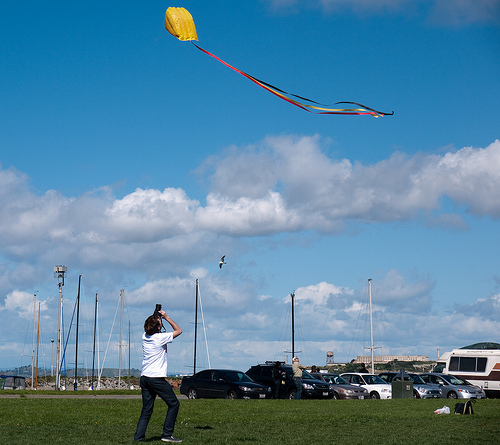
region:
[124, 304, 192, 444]
man is photographing kite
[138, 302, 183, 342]
man is holding camera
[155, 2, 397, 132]
yellow kite in the sky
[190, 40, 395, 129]
kite has long colorful tail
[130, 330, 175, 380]
man wearing white shirt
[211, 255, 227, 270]
seagull flying in sky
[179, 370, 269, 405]
black car is parked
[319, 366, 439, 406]
white car parked next to silver car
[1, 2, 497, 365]
sky is deep blue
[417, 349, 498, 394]
van is parked next to car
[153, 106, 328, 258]
white clouds in the sky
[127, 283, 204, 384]
person taking a photo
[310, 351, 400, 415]
cars parked on the street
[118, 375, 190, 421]
pants on the man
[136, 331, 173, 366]
white shirt on the man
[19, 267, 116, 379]
tall poles next to cars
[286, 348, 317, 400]
person looking up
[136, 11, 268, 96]
object in the air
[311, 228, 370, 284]
blue sky behind clouds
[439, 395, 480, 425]
bag on the ground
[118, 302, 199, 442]
the man with camera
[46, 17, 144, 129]
the sky is blue and clear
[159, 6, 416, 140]
the balloon in the sky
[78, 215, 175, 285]
the clouds in the sky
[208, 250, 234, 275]
the bird in the sky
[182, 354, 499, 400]
the cars are parked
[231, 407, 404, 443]
the grass is green and cut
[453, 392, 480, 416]
the bag on the grass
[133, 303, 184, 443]
the man wearing jeans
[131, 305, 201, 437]
the man wearing a t shirt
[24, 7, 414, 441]
person flying kit on grass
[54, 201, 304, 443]
man holding a camera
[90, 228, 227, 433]
man holding a camera up for picture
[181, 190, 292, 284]
seagull flying in the air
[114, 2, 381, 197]
yellow kite in the air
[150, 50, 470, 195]
tail of yellow kite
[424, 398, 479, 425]
objects laying on the ground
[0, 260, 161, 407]
masts of sail boats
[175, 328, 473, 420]
line of parked cars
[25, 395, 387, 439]
grass field beneath man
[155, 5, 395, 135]
A kite flying in the sky.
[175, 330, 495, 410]
A row of parked cars.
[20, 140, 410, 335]
The sky is cloudy.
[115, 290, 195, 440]
The man is taking a photo.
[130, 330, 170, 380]
A white t-shirt.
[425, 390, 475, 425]
Two bags on the ground.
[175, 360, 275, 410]
A parked black car.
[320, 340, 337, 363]
A water tower.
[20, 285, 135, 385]
Masts of sailboats.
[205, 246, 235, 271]
A seagull flying.